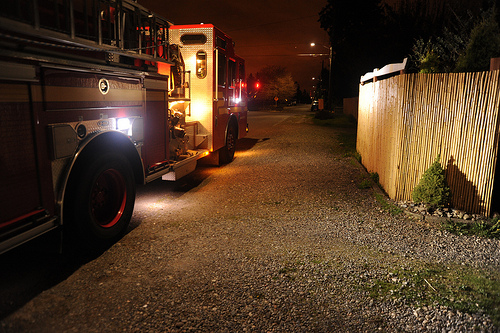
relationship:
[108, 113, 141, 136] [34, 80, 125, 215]
light of truck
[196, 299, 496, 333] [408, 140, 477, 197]
gravel under tree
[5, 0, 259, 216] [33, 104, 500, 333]
truck parked on sidewalk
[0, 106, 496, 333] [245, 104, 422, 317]
gravel on sidewalk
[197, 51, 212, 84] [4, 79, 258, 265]
window on truck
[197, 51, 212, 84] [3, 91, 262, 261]
window on truck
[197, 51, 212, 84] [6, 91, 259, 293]
window on truck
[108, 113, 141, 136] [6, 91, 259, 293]
light on truck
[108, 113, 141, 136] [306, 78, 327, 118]
light on pole